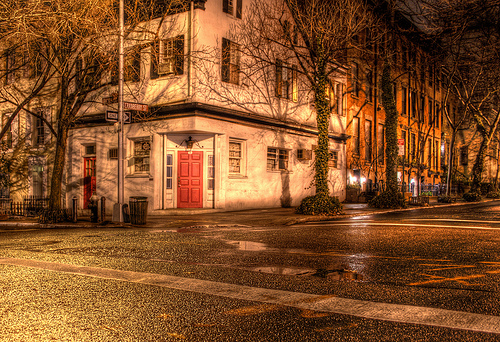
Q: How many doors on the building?
A: 2.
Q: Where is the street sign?
A: On the corner.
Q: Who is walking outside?
A: No one.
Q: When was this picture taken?
A: At night.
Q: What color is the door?
A: Red.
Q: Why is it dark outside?
A: It is night.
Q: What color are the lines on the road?
A: White and yellow.